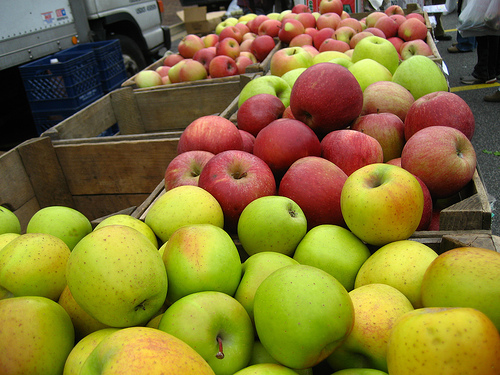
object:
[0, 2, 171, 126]
side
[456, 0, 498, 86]
person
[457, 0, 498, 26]
shirt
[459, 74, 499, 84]
shoe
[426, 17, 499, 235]
ground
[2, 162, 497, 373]
yellow apples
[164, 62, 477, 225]
red apples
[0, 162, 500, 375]
green apple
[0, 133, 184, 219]
crates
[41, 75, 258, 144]
crates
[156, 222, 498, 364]
crates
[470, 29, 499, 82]
pants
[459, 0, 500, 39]
bag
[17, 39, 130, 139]
crates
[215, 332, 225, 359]
stem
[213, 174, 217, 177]
spot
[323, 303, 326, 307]
spots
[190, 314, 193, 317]
spots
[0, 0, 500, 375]
apple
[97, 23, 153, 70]
tyre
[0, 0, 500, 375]
cases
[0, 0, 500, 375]
market